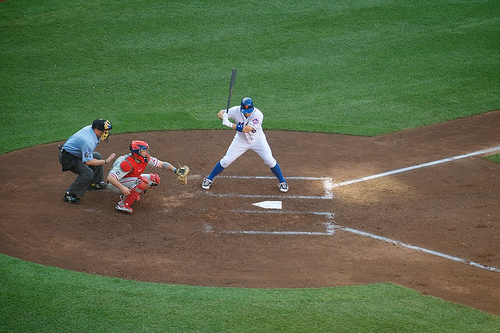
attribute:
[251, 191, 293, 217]
home base — here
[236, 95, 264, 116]
helmet — blue, worn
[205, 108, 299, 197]
player — here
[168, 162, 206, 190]
glove — here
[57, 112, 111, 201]
referee — watching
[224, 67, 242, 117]
bat — held, swung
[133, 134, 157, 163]
mask — here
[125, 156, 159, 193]
gear — red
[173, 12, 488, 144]
field — here, dirt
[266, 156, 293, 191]
sock — blue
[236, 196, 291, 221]
plate — here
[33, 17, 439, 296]
game — here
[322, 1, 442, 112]
grass — lush, here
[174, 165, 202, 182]
mitt — here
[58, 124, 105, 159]
shirt — blue, white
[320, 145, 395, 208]
sun — reflecting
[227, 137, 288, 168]
pants — white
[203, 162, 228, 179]
socks — blue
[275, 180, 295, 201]
shoe — blue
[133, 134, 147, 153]
helmet — red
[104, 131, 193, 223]
catcher — wearing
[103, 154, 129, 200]
uniform — grey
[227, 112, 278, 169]
jersey — white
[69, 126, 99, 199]
umpire — watching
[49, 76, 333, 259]
people — playing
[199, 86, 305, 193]
man — batting, playing